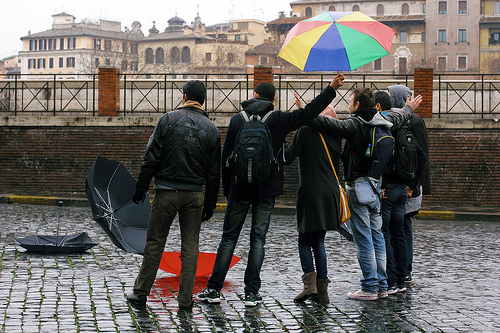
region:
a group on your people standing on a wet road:
[106, 69, 448, 312]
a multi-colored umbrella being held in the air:
[282, 8, 397, 75]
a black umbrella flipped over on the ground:
[82, 153, 155, 259]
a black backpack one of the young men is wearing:
[224, 119, 279, 200]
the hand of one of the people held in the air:
[403, 89, 423, 114]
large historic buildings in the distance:
[14, 10, 277, 91]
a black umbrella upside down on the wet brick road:
[8, 218, 98, 260]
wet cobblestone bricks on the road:
[10, 271, 123, 331]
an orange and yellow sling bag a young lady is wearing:
[319, 134, 354, 226]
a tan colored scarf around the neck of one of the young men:
[173, 98, 207, 111]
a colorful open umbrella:
[279, 10, 404, 78]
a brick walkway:
[11, 264, 101, 326]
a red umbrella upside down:
[156, 251, 232, 278]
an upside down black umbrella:
[11, 201, 109, 269]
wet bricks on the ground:
[441, 225, 498, 312]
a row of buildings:
[37, 11, 264, 76]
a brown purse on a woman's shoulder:
[312, 121, 352, 232]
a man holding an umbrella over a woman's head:
[239, 9, 373, 299]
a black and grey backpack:
[225, 111, 275, 206]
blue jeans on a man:
[345, 196, 396, 324]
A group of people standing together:
[120, 80, 427, 308]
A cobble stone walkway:
[4, 302, 491, 330]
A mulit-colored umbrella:
[280, 8, 398, 78]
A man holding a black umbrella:
[85, 80, 222, 311]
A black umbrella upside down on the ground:
[17, 197, 98, 250]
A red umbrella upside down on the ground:
[148, 247, 241, 276]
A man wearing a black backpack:
[206, 78, 336, 308]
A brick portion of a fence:
[95, 65, 121, 112]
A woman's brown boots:
[293, 271, 333, 305]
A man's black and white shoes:
[192, 289, 264, 307]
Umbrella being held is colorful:
[276, 8, 395, 73]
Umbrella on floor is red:
[155, 245, 242, 280]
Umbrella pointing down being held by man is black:
[82, 142, 158, 261]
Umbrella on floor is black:
[13, 192, 99, 254]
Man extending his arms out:
[290, 80, 425, 299]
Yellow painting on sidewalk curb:
[5, 194, 58, 206]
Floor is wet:
[0, 200, 499, 331]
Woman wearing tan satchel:
[281, 92, 364, 303]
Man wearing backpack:
[197, 70, 344, 311]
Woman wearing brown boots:
[277, 84, 353, 308]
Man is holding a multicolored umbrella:
[195, 8, 417, 317]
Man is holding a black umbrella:
[41, 63, 211, 332]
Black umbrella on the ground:
[16, 186, 92, 265]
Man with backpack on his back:
[298, 83, 433, 312]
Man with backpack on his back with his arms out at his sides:
[283, 95, 447, 310]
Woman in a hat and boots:
[286, 68, 345, 318]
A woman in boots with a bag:
[277, 83, 358, 310]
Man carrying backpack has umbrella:
[193, 13, 423, 294]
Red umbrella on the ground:
[122, 213, 271, 288]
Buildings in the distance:
[14, 0, 480, 73]